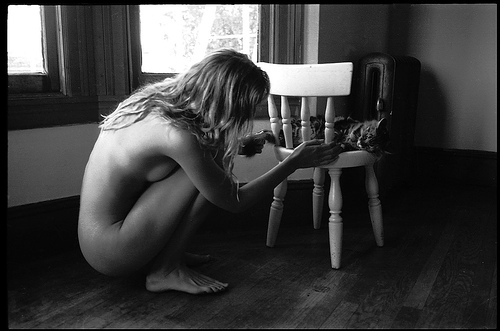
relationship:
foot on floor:
[144, 251, 229, 304] [23, 158, 495, 329]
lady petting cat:
[77, 48, 343, 294] [280, 114, 388, 160]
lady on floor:
[74, 55, 339, 297] [252, 250, 487, 321]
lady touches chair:
[77, 48, 343, 294] [239, 41, 440, 286]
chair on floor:
[254, 54, 391, 271] [4, 170, 499, 330]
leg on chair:
[325, 165, 346, 270] [254, 54, 391, 271]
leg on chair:
[364, 163, 384, 245] [254, 54, 391, 271]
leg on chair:
[310, 164, 326, 227] [254, 54, 391, 271]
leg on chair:
[264, 174, 287, 246] [254, 54, 391, 271]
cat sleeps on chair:
[239, 116, 386, 152] [254, 54, 391, 271]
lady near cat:
[77, 48, 343, 294] [241, 109, 393, 156]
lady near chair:
[77, 48, 343, 294] [254, 54, 391, 271]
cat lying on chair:
[243, 117, 399, 158] [244, 46, 398, 278]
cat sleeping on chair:
[243, 117, 399, 158] [254, 54, 391, 271]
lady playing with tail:
[77, 48, 343, 294] [255, 119, 283, 155]